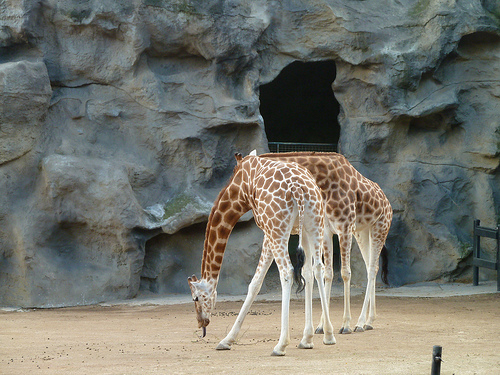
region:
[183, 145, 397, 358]
Two graffics together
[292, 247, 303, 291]
Graffic has black tail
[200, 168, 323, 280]
Graffic has brown spots on him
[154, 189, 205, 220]
Green moss on the rocky cliff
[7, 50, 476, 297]
Rocky cliffs behind graffic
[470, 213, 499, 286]
Fence to the right of the graffics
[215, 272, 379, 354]
White legs on the graffics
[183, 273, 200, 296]
Horns on the graffic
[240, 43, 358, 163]
Big hole in the rocky cliffs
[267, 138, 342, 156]
Metal gate on the other side of the rocky cliffs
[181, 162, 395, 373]
the giraffe is licking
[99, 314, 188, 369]
food is on the ground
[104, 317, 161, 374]
the ground is brown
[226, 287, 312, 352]
the giraffe has white legs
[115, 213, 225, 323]
rocks are behind the giraffe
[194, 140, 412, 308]
the giraffes are brown and white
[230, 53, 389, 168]
an opening is in the rocks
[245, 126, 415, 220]
a fence is in the rocks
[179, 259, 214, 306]
the giraffe has two ears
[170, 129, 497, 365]
two giraffes are pictured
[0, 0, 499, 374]
an outdoor display at a zoo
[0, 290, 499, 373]
a brown dirt ground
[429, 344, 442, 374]
a black metal post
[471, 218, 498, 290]
a black fence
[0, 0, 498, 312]
a rocky concrete wall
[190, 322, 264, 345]
a branch on the ground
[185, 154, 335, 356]
a giraffe bending over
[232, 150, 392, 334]
a giraffe standing on the ground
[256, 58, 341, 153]
a hole in the wall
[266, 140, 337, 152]
a gate inside the hole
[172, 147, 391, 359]
2 giraffes are in the foreground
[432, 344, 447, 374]
some type of fence pole or object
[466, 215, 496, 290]
a fence goes out to the left side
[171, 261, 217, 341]
giraffe's head is leaning down to the ground with his tongue sticking out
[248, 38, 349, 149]
there is a cave in the middle of the rock formation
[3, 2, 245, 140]
the giraffe habitat is made of artificial rocks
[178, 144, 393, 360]
one giraffe is hiding behind the other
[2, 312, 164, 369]
the floor is some type of sandy consistency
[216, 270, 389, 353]
giraffes have tall legs in which to adapt to their environment that eating leaves on trees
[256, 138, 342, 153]
there is a small fence at the entrance of the cave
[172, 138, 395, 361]
giraffe eating something from ground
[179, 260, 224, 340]
head of a giraffe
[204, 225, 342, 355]
four legs of a giraffe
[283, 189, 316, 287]
tail of a giraffe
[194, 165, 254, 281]
neck of giraffe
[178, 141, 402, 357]
two giraffe inside a field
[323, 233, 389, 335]
legs of a giraffe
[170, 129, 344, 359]
giraffe leaning down to eat something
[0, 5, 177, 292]
a rocky platform and wall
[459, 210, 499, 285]
a two layer barricade